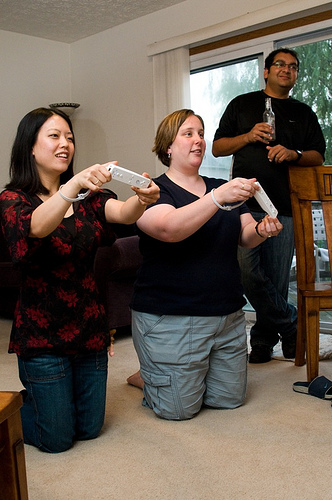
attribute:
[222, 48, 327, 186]
man — young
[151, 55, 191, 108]
blinds — white 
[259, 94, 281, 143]
bottle — glass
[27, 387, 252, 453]
knees — two pairs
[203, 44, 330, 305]
man — indian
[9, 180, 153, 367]
shirt — black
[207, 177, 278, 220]
remote — two and white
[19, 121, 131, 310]
woman — asian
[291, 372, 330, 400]
slipper — one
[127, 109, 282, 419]
woman — blond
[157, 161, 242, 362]
lady — heavyset and young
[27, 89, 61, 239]
hair — long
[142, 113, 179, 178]
hair — short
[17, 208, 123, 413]
woman — asian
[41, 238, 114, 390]
woman — asian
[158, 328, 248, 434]
pants — gray, cotton and cargo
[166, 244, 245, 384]
woman — blond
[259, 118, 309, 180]
man — indian